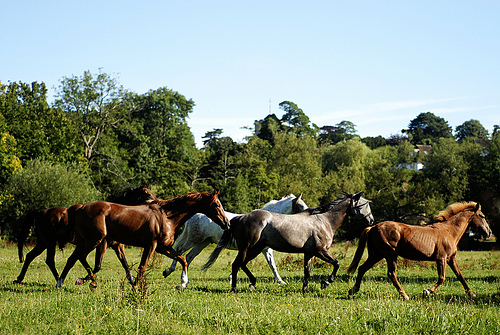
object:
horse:
[344, 200, 493, 302]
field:
[0, 212, 499, 334]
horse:
[54, 186, 232, 301]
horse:
[162, 191, 310, 288]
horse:
[202, 189, 376, 293]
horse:
[13, 184, 160, 290]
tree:
[0, 157, 104, 243]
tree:
[215, 169, 253, 215]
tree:
[0, 130, 27, 207]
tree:
[274, 149, 324, 215]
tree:
[397, 170, 447, 223]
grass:
[0, 228, 500, 334]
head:
[468, 201, 493, 240]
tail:
[345, 226, 373, 275]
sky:
[0, 0, 500, 148]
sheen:
[253, 209, 316, 248]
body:
[231, 208, 339, 291]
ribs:
[405, 228, 438, 259]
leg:
[158, 245, 190, 292]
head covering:
[351, 191, 374, 226]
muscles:
[152, 209, 177, 250]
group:
[0, 200, 499, 334]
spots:
[187, 215, 204, 245]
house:
[389, 143, 435, 171]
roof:
[415, 142, 434, 155]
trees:
[228, 120, 322, 243]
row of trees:
[450, 118, 498, 243]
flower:
[103, 304, 116, 312]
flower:
[277, 300, 296, 312]